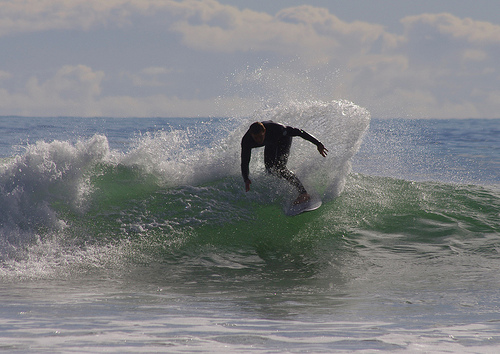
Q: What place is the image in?
A: It is at the sea.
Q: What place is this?
A: It is a sea.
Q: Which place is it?
A: It is a sea.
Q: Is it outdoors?
A: Yes, it is outdoors.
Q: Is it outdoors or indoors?
A: It is outdoors.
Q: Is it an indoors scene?
A: No, it is outdoors.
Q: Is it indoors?
A: No, it is outdoors.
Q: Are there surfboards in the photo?
A: Yes, there is a surfboard.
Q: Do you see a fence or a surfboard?
A: Yes, there is a surfboard.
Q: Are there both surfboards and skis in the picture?
A: No, there is a surfboard but no skis.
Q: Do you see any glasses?
A: No, there are no glasses.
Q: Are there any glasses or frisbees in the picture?
A: No, there are no glasses or frisbees.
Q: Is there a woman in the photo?
A: No, there are no women.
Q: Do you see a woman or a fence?
A: No, there are no women or fences.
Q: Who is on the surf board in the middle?
A: The man is on the surfboard.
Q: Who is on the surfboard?
A: The man is on the surfboard.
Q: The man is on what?
A: The man is on the surfboard.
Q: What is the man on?
A: The man is on the surfboard.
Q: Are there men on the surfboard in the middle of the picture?
A: Yes, there is a man on the surfboard.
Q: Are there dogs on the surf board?
A: No, there is a man on the surf board.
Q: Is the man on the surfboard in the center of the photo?
A: Yes, the man is on the surfboard.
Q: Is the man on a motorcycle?
A: No, the man is on the surfboard.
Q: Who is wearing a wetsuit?
A: The man is wearing a wetsuit.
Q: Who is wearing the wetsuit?
A: The man is wearing a wetsuit.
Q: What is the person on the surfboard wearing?
A: The man is wearing a wetsuit.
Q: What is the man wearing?
A: The man is wearing a wetsuit.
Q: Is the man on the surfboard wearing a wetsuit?
A: Yes, the man is wearing a wetsuit.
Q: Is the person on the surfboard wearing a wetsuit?
A: Yes, the man is wearing a wetsuit.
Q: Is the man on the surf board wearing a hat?
A: No, the man is wearing a wetsuit.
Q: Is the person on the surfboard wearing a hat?
A: No, the man is wearing a wetsuit.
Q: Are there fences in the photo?
A: No, there are no fences.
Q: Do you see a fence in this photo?
A: No, there are no fences.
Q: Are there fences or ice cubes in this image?
A: No, there are no fences or ice cubes.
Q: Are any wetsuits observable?
A: Yes, there is a wetsuit.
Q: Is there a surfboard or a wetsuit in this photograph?
A: Yes, there is a wetsuit.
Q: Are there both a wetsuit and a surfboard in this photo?
A: Yes, there are both a wetsuit and a surfboard.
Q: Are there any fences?
A: No, there are no fences.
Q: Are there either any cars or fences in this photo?
A: No, there are no fences or cars.